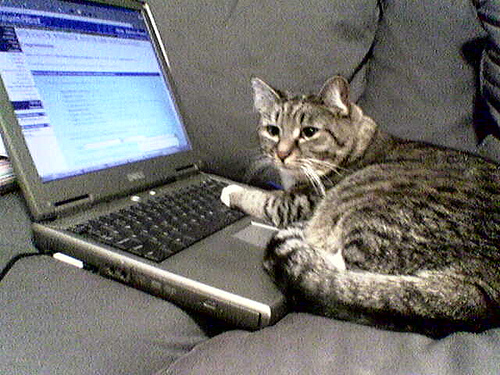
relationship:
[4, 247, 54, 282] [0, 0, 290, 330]
cord near laptop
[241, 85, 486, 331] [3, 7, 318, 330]
cat on lap top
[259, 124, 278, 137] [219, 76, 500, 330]
eyes on cat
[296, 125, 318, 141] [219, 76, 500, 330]
eye on cat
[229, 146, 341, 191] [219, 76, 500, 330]
whiskers on cat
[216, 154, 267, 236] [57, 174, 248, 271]
paw on keyboard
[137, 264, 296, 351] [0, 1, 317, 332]
dvd on laptop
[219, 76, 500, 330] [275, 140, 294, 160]
cat with nose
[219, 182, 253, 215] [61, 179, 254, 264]
cat's paw on keyboard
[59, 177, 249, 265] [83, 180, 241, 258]
keys of laptop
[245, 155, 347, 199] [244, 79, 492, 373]
whiskers on cat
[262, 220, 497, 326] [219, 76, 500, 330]
tail of cat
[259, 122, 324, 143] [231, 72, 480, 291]
eyes of cat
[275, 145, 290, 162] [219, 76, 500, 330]
nose of cat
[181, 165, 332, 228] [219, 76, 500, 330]
front leg of cat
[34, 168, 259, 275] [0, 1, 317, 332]
keyboard on laptop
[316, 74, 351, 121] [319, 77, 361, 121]
ear of cat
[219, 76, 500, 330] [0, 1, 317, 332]
cat near laptop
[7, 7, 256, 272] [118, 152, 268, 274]
laptop has keyboard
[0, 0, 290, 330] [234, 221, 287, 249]
laptop has touchpad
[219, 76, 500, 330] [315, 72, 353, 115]
cat has ear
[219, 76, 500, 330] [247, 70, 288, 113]
cat has ear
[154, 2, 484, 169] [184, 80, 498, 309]
cushion behind cat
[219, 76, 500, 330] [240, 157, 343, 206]
cat has whiskers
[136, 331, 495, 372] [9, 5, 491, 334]
cushion on couch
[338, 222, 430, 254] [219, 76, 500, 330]
stripe on cat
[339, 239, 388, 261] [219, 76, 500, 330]
stripe on cat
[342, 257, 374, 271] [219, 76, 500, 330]
stripe on cat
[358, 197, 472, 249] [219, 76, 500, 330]
stripe on cat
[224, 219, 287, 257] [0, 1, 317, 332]
mouse on laptop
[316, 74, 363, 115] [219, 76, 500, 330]
ear of cat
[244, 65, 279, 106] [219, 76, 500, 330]
ear of cat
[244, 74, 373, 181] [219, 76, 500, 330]
head of cat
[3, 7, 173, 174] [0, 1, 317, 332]
screen of laptop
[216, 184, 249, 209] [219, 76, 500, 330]
paw of cat